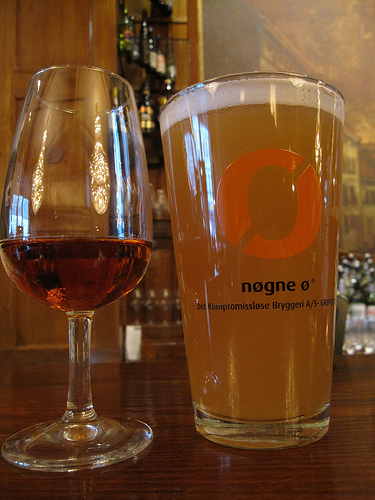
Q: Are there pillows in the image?
A: No, there are no pillows.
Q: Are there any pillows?
A: No, there are no pillows.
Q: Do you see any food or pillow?
A: No, there are no pillows or food.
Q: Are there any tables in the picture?
A: Yes, there is a table.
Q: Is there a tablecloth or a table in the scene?
A: Yes, there is a table.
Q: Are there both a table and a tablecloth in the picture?
A: No, there is a table but no tablecloths.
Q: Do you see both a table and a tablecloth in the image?
A: No, there is a table but no tablecloths.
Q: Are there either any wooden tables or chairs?
A: Yes, there is a wood table.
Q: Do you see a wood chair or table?
A: Yes, there is a wood table.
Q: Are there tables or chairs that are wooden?
A: Yes, the table is wooden.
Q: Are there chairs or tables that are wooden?
A: Yes, the table is wooden.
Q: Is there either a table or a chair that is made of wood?
A: Yes, the table is made of wood.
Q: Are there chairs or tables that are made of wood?
A: Yes, the table is made of wood.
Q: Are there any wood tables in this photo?
A: Yes, there is a wood table.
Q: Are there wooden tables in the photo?
A: Yes, there is a wood table.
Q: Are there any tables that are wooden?
A: Yes, there is a table that is wooden.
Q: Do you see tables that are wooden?
A: Yes, there is a table that is wooden.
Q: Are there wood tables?
A: Yes, there is a table that is made of wood.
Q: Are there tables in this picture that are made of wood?
A: Yes, there is a table that is made of wood.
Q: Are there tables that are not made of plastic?
A: Yes, there is a table that is made of wood.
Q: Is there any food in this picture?
A: No, there is no food.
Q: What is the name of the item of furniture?
A: The piece of furniture is a table.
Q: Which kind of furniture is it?
A: The piece of furniture is a table.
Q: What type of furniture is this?
A: This is a table.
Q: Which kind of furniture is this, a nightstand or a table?
A: This is a table.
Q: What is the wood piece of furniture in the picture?
A: The piece of furniture is a table.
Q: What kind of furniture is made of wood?
A: The furniture is a table.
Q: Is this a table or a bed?
A: This is a table.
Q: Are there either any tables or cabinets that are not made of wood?
A: No, there is a table but it is made of wood.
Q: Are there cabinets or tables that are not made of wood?
A: No, there is a table but it is made of wood.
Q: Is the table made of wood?
A: Yes, the table is made of wood.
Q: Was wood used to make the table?
A: Yes, the table is made of wood.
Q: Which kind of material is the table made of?
A: The table is made of wood.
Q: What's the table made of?
A: The table is made of wood.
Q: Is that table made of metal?
A: No, the table is made of wood.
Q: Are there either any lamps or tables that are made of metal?
A: No, there is a table but it is made of wood.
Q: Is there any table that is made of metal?
A: No, there is a table but it is made of wood.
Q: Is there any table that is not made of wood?
A: No, there is a table but it is made of wood.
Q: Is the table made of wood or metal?
A: The table is made of wood.